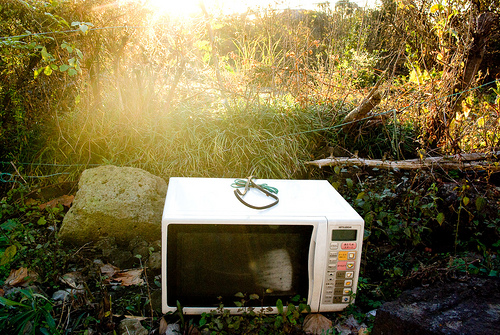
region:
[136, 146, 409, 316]
microwave sitting near rock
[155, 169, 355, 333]
microwave is mostly white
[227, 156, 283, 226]
microwave has black and green cord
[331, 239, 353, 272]
microwave has pink buttons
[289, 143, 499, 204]
downed tree behind microwave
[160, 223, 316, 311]
microwave has black window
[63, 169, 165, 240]
large rock next to microwave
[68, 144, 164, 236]
large rock is grey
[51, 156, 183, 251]
large rock is jagged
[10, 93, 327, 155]
thick grasses behind rock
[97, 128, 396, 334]
a white microwave outside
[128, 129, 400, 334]
a microwave in the grass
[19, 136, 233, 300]
a rock on the ground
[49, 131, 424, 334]
a white microwave on the ground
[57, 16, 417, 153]
an area with bushes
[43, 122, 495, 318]
a large rock on ground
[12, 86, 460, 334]
a rock and microwave on ground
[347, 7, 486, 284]
dead trees on the ground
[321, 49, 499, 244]
broken trees on the ground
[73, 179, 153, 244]
Large rock near microwave.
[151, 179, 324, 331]
White microwave laying on the ground.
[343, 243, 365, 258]
Pink button on microwave.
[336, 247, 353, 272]
Orange button on microwave.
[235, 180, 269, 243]
Black and blue object on top of microwave.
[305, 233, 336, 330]
White handle on door of microwave.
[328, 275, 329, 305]
White buttons on microwave.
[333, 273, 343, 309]
Gray buttons on microwave.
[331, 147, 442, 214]
Large stick on ground near microwave.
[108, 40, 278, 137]
Sun shinning in the distance.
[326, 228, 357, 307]
dials on a microwave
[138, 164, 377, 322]
a microwave oven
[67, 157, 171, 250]
a rock in the woods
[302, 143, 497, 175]
a dry twig in the woods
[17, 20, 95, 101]
foliage in the woods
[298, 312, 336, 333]
a rock on the ground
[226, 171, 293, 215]
a rope on a microwave oven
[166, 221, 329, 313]
the front door of a microwave oven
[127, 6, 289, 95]
the sun shining through some trees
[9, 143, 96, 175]
a piece of string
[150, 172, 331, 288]
White microwave on ground.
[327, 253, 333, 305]
White buttons on microwave.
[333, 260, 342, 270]
Pink button on microwave.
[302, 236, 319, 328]
White door handle on microwave.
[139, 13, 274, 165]
Sun shinning in distance.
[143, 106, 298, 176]
Tall grass behind microwave.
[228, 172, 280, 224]
Black and blue object on top of microwave.